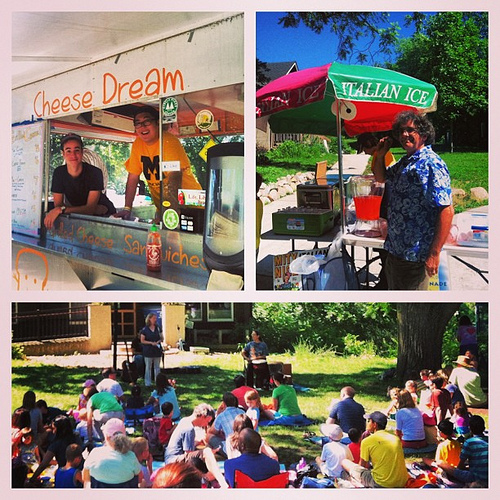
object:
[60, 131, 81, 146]
hat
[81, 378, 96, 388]
hat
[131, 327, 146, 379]
man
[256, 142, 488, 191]
grass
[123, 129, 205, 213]
shirt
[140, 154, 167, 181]
word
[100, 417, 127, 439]
hat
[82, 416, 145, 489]
man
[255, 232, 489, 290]
walkway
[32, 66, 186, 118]
writing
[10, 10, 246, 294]
truck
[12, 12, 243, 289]
side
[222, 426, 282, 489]
man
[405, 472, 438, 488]
pillow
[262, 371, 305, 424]
woman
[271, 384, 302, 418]
shirt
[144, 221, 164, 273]
bottle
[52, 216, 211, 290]
counter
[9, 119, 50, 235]
board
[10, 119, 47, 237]
menu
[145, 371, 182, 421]
person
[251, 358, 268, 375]
drum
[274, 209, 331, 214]
cooler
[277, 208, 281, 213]
bottle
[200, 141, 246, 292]
napkin dispenser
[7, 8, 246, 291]
food truck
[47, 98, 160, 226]
window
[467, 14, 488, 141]
tree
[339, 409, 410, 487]
man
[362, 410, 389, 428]
hat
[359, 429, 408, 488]
shirt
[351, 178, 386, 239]
glass container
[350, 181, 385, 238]
italian ice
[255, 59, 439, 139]
umbrella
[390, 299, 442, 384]
tree trunk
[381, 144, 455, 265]
shirt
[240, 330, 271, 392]
speaker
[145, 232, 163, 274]
hot sauce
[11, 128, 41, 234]
words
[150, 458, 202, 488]
people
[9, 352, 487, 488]
grass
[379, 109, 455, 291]
man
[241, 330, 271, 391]
woman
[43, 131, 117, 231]
man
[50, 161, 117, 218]
shirt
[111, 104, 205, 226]
man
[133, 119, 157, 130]
glasses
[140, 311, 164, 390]
woman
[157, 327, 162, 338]
microphone